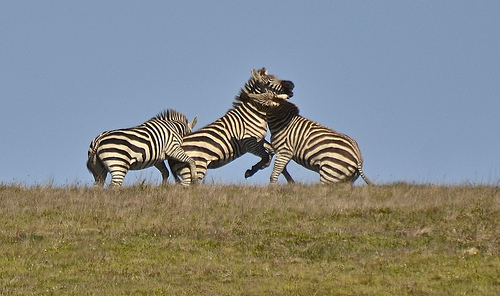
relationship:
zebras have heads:
[80, 62, 378, 191] [245, 67, 286, 126]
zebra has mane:
[253, 78, 363, 195] [275, 90, 301, 114]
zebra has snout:
[253, 78, 363, 195] [238, 86, 267, 112]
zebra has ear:
[253, 78, 363, 195] [263, 84, 272, 95]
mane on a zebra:
[275, 90, 301, 114] [253, 78, 363, 195]